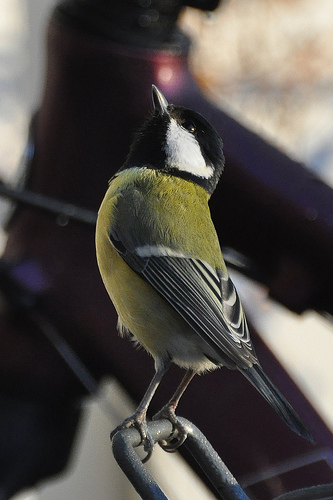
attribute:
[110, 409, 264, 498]
stand — iron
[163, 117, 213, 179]
spot — white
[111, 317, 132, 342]
feathers — white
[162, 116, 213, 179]
cheek feathers — white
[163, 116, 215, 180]
skin — white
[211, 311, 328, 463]
feathers — black, gray, tail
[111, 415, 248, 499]
handle — metal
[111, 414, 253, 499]
hook — gray, metal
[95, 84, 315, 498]
bird — small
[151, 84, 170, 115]
beak — black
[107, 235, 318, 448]
feathers — black, white, bird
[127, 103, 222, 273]
bird — small, yellow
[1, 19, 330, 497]
object — red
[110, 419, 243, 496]
metal — gray, blue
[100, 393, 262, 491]
stand — iron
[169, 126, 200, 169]
feather — white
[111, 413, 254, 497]
object — metal